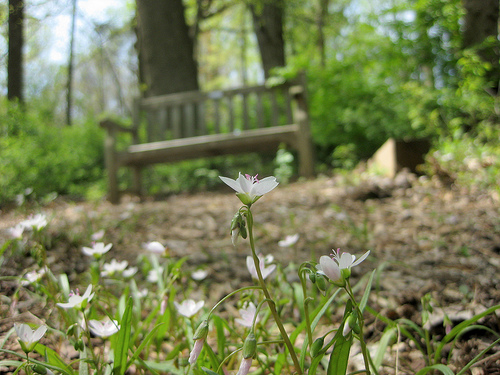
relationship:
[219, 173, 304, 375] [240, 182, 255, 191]
flower colored white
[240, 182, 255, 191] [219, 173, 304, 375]
white small flower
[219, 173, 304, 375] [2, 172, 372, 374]
flower in flowers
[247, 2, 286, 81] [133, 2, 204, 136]
tree has trunk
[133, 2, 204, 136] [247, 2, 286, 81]
trunk has tree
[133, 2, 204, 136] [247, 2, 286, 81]
trunk of tree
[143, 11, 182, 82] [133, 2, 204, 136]
brown colored tree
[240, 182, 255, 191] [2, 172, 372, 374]
white colored flowers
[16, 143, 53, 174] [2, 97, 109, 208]
green colored leaves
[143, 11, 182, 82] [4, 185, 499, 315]
brown colored ground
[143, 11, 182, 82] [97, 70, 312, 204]
brown colored bench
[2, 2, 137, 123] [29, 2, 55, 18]
sky colored blue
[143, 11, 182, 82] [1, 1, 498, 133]
brown colored woods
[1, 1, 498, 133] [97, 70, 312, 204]
woods behind bench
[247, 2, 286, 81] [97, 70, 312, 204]
tree behind bench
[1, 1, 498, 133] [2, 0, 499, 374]
day time picture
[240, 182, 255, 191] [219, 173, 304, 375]
white growing flower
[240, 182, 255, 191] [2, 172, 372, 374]
white growing flowers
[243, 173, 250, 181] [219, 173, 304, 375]
pink center flower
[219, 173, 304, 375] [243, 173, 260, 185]
flower has center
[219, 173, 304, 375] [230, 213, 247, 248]
flower has bud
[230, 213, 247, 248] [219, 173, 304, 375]
bud additional flower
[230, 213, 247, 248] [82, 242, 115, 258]
bud not opened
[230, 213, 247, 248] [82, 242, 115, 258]
bud additional opened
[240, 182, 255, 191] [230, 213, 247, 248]
white tip bud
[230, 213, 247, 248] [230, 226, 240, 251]
bud has tip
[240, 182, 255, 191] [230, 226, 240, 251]
white bud tip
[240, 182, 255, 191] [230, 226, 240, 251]
white additional tip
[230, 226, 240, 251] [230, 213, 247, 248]
tip additional bud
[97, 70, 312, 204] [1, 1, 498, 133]
bench in background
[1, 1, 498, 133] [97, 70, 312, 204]
background with bench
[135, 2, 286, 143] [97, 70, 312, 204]
trees behind bench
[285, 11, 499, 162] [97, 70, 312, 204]
bushes behind bench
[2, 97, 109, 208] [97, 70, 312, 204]
bush behind bench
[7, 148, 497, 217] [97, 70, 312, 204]
grass behind bench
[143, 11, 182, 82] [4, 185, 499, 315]
brown ground ground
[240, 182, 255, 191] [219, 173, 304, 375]
white pink flower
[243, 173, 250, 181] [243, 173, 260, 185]
pink small center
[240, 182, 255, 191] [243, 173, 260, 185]
white pink center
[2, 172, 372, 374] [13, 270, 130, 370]
flowers in cluster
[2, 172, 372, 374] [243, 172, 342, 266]
flowers with centers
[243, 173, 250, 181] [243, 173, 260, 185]
pink inside center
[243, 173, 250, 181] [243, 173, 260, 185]
pink clustered center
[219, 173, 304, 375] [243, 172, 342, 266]
flower clustered centers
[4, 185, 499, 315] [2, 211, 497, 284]
trail on trail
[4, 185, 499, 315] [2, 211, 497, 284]
trail scattered trail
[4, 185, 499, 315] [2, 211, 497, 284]
trail upon trail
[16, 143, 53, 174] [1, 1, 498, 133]
green forest background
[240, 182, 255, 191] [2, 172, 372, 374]
white small flowers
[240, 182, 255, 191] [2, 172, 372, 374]
white grouped flowers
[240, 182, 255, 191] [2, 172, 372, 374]
white delicate flowers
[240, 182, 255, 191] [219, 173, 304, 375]
white grouped flower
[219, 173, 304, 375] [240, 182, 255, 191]
flower small white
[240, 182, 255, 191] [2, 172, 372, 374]
white tiny flowers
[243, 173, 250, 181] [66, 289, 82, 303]
pink flowered stamen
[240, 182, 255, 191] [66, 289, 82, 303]
white flower stamen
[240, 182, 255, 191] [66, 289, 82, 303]
white pink stamen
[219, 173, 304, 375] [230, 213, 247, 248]
flower blossems closed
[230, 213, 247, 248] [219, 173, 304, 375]
closed flower flower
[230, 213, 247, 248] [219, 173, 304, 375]
closed white flower